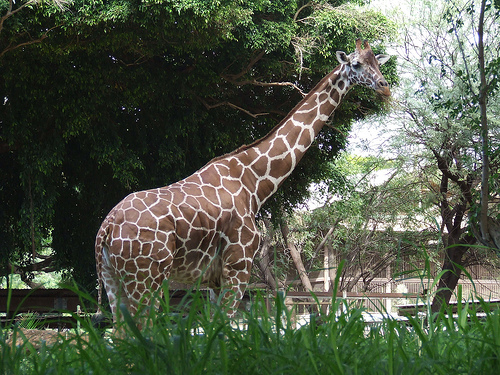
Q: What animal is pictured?
A: A giraffe.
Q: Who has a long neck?
A: The giraffe has a long neck.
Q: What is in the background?
A: A building.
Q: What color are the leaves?
A: Green.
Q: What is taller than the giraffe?
A: The tree.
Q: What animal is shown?
A: Giraffe.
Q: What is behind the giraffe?
A: Tree.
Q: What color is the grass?
A: Green.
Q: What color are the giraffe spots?
A: Brown.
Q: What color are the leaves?
A: Green.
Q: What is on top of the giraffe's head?
A: Horns.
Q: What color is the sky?
A: Blue.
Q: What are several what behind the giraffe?
A: Trees.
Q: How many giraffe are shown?
A: One.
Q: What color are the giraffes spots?
A: Brown.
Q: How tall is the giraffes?
A: As the trees.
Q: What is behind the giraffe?
A: Trees.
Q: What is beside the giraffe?
A: Plants.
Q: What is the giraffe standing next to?
A: Tree.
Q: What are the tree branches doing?
A: Hanging.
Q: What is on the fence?
A: Gate.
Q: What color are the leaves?
A: Green.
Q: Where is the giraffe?
A: In a pen.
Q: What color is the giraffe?
A: Brown and white.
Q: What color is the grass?
A: Green.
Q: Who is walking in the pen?
A: The giraffe.